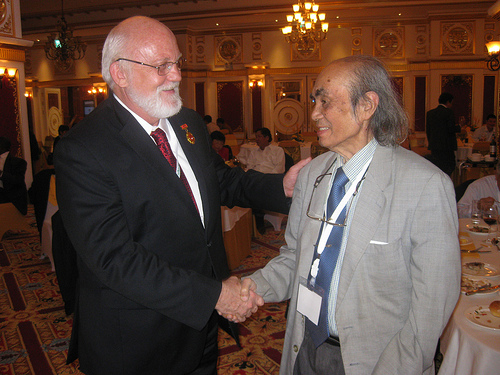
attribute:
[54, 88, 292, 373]
suit — black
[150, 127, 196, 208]
tie — red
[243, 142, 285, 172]
shirt — white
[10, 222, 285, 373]
rug — designed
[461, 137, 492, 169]
dishes — stacked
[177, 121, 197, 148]
medal — red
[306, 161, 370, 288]
lanyard — white